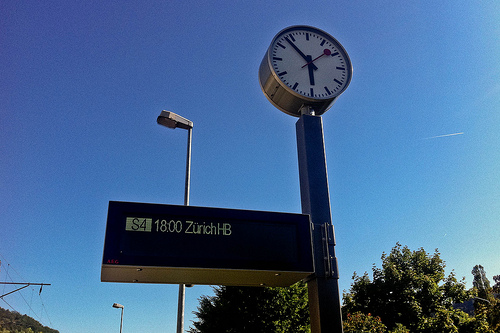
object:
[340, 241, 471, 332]
tree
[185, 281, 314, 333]
tree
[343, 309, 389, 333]
tree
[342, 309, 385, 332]
tall tree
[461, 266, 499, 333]
tall tree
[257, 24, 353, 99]
clock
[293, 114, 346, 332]
pole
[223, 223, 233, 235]
letters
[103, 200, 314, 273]
sign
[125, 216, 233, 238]
s4 18:00 zurich hb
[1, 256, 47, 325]
wires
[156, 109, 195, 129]
street light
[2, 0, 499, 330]
sky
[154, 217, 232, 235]
18:00 zurich hb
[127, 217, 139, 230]
letters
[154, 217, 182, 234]
time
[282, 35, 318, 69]
hands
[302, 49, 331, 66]
second hand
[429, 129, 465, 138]
line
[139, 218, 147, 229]
numbers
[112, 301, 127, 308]
street light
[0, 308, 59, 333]
trees